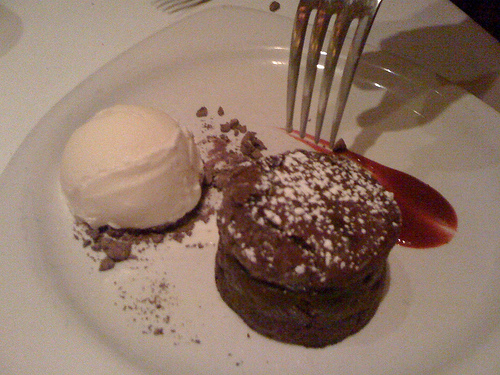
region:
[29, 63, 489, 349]
The dessert on the plate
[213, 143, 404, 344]
The cake is the color brown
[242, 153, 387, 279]
The powdered sugar on the cake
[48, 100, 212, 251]
The ice cream on the side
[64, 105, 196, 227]
The color of the ice cream is white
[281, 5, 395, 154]
The fork on the plate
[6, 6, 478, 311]
The plate is square shaped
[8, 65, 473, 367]
A dish of chocolate cake and vanilla ice cream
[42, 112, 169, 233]
vanilla ice cream on plate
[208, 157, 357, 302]
brownie on the plate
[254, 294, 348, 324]
the brownie is brown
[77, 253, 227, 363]
crumbs on the plate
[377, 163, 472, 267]
sauce on the plate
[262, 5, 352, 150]
fork on the plate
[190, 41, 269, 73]
the plate is glass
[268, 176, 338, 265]
sugar on the brownie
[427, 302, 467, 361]
the plate is white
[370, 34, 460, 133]
shadow of the fork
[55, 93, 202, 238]
the ice cream on the plate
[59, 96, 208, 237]
the vanilla ice cream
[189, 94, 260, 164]
the choclate crumbs on the white plate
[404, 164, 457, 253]
the red syrup on the plate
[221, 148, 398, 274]
the powder on the brownie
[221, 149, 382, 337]
the chocolate brownie on the plate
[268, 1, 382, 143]
the prongs of the fork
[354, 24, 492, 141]
the hands shadow on the table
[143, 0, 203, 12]
the fork on the white tale top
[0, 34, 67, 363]
the round white plate on the table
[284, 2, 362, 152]
The silver fork is ready for desert.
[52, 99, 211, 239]
The white ice cream looks delicious.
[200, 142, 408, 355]
The brown desert has white powder on top.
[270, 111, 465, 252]
The red sauce looks yummy.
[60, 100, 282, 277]
The brown powder looks like chocolate powder.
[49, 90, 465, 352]
This is a very good looking desert.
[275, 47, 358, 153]
I have forks that look like this at home.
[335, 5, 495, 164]
This is the shadow of the person holding the fork.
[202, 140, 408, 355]
This is the type of desert I would like to taste.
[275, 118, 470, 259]
The red sauce looks sweet.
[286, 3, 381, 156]
silver metal fork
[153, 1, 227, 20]
shadow of fork on table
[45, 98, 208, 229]
dollop of vanilla ice cream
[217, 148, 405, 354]
chocolate pastry on plate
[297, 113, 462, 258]
red sauce on plate